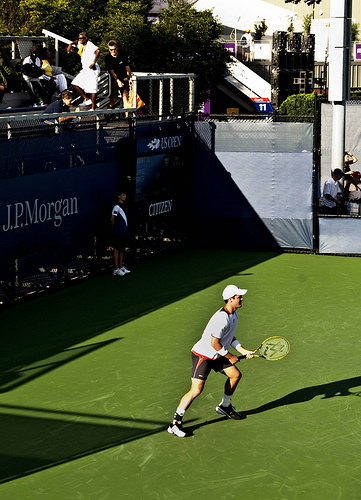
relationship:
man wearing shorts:
[62, 33, 106, 112] [69, 68, 100, 95]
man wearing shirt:
[62, 33, 106, 112] [74, 38, 101, 69]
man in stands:
[62, 33, 106, 112] [0, 32, 197, 131]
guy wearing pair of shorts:
[166, 284, 254, 439] [186, 347, 237, 390]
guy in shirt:
[166, 284, 254, 439] [190, 308, 237, 363]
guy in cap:
[166, 284, 254, 439] [219, 283, 247, 300]